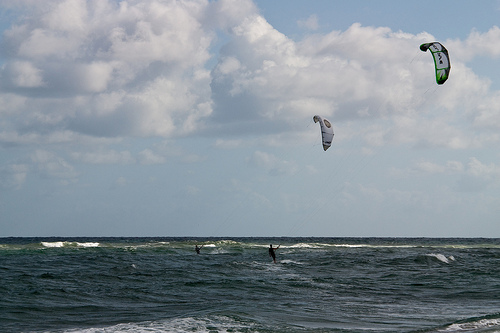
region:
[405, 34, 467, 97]
sail in sky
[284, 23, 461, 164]
two sails in sky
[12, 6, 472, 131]
white clouds in sky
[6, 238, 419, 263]
wave in ocean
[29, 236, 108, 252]
white top of ocean wave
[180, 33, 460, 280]
two people ski surfing in water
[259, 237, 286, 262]
silhouette of person skiing in ocean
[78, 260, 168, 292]
dark line ripples in water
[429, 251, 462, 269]
whtie froth on top of water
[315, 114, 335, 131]
red circle in middle of sail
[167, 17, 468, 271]
two people that are being pulled by sails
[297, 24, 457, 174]
two sails in the sky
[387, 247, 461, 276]
an ocean wave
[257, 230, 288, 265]
a person in the water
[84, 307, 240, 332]
white foam on the ocean surface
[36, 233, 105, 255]
the white caps of a wave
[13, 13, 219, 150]
puffy clouds in the sky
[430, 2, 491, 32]
a patch of clear sky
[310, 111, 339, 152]
a white and black sail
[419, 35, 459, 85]
a white, black, and green sail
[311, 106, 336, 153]
White kite in the sky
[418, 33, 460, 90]
Black and green kite in the sky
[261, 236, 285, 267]
Person para sailing in the ocean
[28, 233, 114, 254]
Waves crashing into the ocean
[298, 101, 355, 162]
White Para sail in the air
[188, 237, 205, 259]
person parasailing on the ocean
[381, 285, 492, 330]
water washing a shore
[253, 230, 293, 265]
man parasailing through the water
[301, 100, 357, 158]
para sail in a cloudy ski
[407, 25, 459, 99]
Green para sail in the sky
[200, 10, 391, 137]
kites are in the sky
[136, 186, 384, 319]
the men are flying kites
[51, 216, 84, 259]
the water has waves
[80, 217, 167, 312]
the waves are rough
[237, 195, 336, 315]
the men are holding strings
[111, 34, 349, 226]
the sky is cloudy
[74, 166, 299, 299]
the sky is calm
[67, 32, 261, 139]
the clouds are white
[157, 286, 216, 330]
the water splashes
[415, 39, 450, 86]
sail is in the air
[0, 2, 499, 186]
massive clouds are in the sky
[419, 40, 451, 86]
sail is attached to a cord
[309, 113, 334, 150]
sail is attached to a cord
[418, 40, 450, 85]
sail has a human hanging on to it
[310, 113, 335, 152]
sail has a human hanging on to it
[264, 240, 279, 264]
human hangs on to sail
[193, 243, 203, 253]
human hangs on to sail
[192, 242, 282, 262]
humans are kite boarding